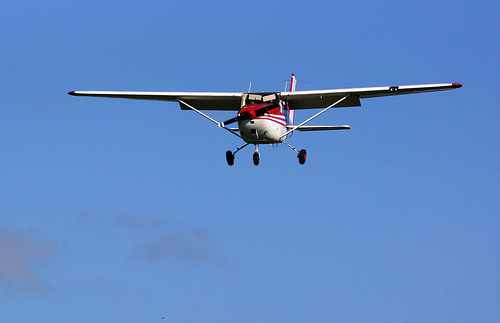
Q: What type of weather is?
A: It is clear.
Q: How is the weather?
A: It is clear.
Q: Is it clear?
A: Yes, it is clear.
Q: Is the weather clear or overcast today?
A: It is clear.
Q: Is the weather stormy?
A: No, it is clear.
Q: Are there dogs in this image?
A: No, there are no dogs.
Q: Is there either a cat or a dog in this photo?
A: No, there are no dogs or cats.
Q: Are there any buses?
A: No, there are no buses.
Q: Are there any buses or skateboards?
A: No, there are no buses or skateboards.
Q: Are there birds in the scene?
A: No, there are no birds.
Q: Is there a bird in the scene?
A: No, there are no birds.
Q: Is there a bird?
A: No, there are no birds.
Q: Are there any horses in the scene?
A: No, there are no horses.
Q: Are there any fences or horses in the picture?
A: No, there are no horses or fences.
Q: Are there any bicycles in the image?
A: No, there are no bicycles.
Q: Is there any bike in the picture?
A: No, there are no bikes.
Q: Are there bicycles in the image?
A: No, there are no bicycles.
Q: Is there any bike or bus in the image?
A: No, there are no bikes or buses.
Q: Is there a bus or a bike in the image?
A: No, there are no bikes or buses.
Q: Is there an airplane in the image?
A: Yes, there is an airplane.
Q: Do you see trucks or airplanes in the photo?
A: Yes, there is an airplane.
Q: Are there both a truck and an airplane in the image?
A: No, there is an airplane but no trucks.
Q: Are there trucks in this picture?
A: No, there are no trucks.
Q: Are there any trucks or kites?
A: No, there are no trucks or kites.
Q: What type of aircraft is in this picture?
A: The aircraft is an airplane.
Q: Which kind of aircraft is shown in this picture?
A: The aircraft is an airplane.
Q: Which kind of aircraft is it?
A: The aircraft is an airplane.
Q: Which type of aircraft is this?
A: This is an airplane.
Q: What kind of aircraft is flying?
A: The aircraft is an airplane.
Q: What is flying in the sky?
A: The airplane is flying in the sky.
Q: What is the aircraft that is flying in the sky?
A: The aircraft is an airplane.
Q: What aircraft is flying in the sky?
A: The aircraft is an airplane.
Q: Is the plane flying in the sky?
A: Yes, the plane is flying in the sky.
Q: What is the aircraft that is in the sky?
A: The aircraft is an airplane.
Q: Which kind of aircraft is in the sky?
A: The aircraft is an airplane.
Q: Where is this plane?
A: The plane is in the sky.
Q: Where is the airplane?
A: The plane is in the sky.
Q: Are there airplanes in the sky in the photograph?
A: Yes, there is an airplane in the sky.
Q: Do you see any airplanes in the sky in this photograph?
A: Yes, there is an airplane in the sky.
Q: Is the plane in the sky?
A: Yes, the plane is in the sky.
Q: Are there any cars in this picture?
A: No, there are no cars.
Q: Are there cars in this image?
A: No, there are no cars.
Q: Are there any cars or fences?
A: No, there are no cars or fences.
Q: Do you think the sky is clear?
A: Yes, the sky is clear.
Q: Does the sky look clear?
A: Yes, the sky is clear.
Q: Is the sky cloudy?
A: No, the sky is clear.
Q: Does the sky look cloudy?
A: No, the sky is clear.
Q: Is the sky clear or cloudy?
A: The sky is clear.